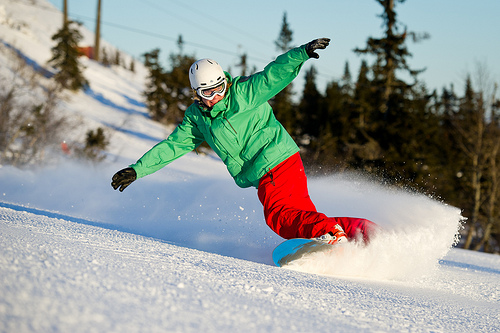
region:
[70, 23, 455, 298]
person snowboarding in snow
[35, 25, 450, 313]
person snowboarding in snow during the day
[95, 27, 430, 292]
person snowboarding very nicely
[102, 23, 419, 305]
person coasting on board in snow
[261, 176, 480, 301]
snowboard kicking up snow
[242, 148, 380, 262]
person wearing red pants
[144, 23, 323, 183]
person wearing a green jacket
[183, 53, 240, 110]
person wearing helmet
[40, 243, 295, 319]
patch of some hard snow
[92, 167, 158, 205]
right hand wearing glove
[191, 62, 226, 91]
a white helmet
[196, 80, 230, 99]
a pair of white snow goggles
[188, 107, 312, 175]
a green coat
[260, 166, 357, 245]
a pair of red pants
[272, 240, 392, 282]
a blue snowboard spraying snow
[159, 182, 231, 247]
snow being sprayed into the air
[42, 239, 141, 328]
clean, untouched snow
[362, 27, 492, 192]
evergreens in the background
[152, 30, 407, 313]
a person snowboarding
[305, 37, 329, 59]
a black glove in the air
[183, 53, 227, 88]
a white helmet on the person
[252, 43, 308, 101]
the arm of a person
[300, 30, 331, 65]
the hand of a person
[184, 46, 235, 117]
the head of a person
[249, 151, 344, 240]
the legs of a person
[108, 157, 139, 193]
a black glove on the person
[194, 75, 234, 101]
a pair of goggles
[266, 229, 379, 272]
a snowboard under the person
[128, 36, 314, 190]
a green coat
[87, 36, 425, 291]
person snowboarding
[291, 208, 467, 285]
white snow being kicked up from the snowboard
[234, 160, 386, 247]
puffy orange snow pants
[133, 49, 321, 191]
puffy green jacket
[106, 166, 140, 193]
black leather glove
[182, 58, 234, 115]
white helmet with white and blue goggles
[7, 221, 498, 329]
white snow laying on the ground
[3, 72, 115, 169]
small trees with no leaves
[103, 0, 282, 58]
black wires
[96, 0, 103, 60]
bottom of a wooden pole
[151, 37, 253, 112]
The person is wearing a helmet.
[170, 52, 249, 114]
The person is wearing goggles.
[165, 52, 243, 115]
The helmet is white.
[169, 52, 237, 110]
The goggles are white.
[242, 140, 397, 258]
The person is wearing red pants.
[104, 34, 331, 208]
The person is wearing a green top.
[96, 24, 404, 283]
The person is snowboarding.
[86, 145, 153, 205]
The person is wearing black gloves.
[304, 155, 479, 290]
A spray of snow.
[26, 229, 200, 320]
The snow is white.